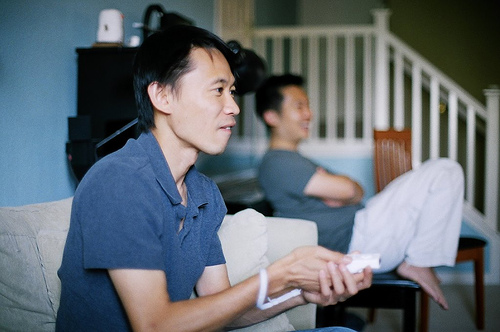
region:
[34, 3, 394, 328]
a man playing wii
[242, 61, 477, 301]
a man laughing at a friend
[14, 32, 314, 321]
a man sitting on a couch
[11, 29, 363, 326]
a man in a blue shirt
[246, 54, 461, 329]
a man sitting on a chair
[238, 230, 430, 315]
a white controller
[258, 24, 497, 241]
a staircase banister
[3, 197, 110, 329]
a tan couch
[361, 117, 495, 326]
a brown wooden chair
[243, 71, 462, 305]
a bare foot man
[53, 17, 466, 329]
two men sitting down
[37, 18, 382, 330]
man holding game controller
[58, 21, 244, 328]
man wearing grey shirt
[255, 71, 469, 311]
man sitting with knees bent up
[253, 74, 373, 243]
man with arms crossed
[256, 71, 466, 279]
man wearing white pants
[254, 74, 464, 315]
man sitting with bare feet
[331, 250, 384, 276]
a remote game controller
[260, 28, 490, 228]
a white staircase banister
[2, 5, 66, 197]
a grey painted wall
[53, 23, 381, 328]
man playing video game with remote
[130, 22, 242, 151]
a man with dark black hair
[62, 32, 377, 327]
man wearing a grey polo shirt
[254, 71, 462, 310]
man with legs bent on chair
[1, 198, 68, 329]
fabric of coach man is sitting on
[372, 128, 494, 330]
wooden chair in the background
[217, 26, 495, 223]
a white banister staircase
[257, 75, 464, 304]
a man wearing white pants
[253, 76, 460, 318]
a man with knees bent and bare feet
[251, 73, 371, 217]
a man with arms crossed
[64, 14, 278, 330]
dark haired man with blue shirt on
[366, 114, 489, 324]
brown wooden chair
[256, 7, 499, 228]
white railing for staircase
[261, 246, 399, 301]
Nintendo Wii remote in mans hands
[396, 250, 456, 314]
bare foot of man sitting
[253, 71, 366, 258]
Man smiling in background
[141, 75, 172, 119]
right ear of a man holding wii remote.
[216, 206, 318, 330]
part of a light colored couch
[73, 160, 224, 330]
blue shirt on a man sitting playing wii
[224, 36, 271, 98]
top of a black colored light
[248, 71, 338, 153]
This guy is laughing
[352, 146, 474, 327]
He is wearing white pants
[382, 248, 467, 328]
He is not wearing shoes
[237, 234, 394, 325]
He has a game control wrapped around his wrist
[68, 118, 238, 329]
He is wearing a blue shirt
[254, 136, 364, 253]
he is wearing a grey shirt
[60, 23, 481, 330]
There are two men sitting down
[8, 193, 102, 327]
The couch is grey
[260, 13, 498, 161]
The stair rail is white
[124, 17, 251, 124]
His hair is black